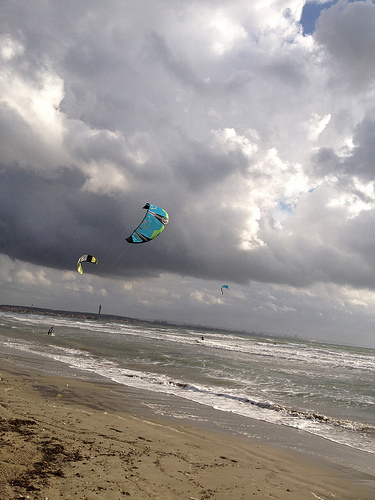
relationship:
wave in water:
[178, 378, 194, 393] [0, 306, 375, 483]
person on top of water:
[45, 327, 54, 339] [71, 331, 88, 354]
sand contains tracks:
[3, 447, 277, 498] [48, 423, 92, 431]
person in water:
[45, 327, 54, 339] [0, 306, 375, 483]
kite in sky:
[129, 201, 170, 250] [174, 4, 367, 327]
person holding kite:
[45, 327, 54, 339] [129, 201, 170, 250]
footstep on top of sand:
[127, 465, 138, 472] [3, 447, 277, 498]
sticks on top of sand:
[49, 440, 59, 463] [3, 447, 277, 498]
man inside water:
[198, 333, 209, 344] [71, 331, 88, 354]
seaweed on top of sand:
[7, 421, 83, 498] [3, 447, 277, 498]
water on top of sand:
[71, 331, 88, 354] [3, 447, 277, 498]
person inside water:
[45, 327, 54, 339] [0, 306, 375, 483]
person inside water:
[200, 328, 206, 340] [71, 331, 88, 354]